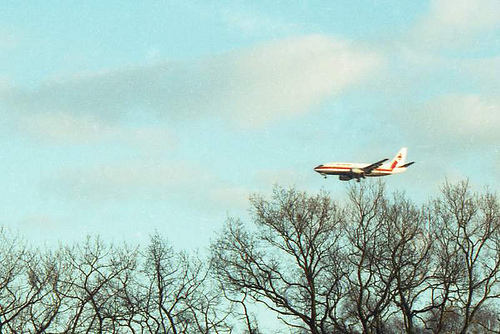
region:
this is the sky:
[19, 22, 53, 45]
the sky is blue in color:
[28, 29, 50, 47]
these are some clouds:
[40, 42, 476, 134]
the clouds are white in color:
[251, 42, 332, 88]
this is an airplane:
[303, 150, 413, 187]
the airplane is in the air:
[313, 147, 413, 177]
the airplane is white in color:
[326, 161, 339, 166]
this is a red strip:
[319, 163, 351, 170]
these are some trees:
[5, 185, 493, 327]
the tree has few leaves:
[268, 202, 323, 229]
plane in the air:
[305, 145, 425, 185]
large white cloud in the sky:
[34, 42, 359, 139]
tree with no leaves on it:
[5, 187, 499, 332]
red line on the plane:
[321, 162, 348, 173]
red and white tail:
[379, 141, 424, 171]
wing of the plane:
[362, 150, 390, 176]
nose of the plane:
[311, 159, 328, 177]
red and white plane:
[282, 135, 435, 195]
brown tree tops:
[2, 185, 497, 329]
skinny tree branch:
[239, 302, 253, 324]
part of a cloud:
[268, 64, 330, 109]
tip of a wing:
[381, 150, 397, 157]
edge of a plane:
[362, 159, 378, 174]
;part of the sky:
[141, 137, 206, 202]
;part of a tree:
[224, 284, 254, 314]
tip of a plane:
[290, 148, 336, 175]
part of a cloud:
[225, 78, 268, 119]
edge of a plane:
[318, 162, 332, 173]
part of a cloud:
[248, 52, 300, 107]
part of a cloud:
[196, 53, 261, 133]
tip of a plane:
[309, 161, 317, 190]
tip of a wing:
[363, 134, 394, 181]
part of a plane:
[329, 160, 347, 177]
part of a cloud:
[239, 90, 294, 158]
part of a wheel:
[319, 168, 330, 183]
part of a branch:
[297, 255, 314, 309]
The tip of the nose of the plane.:
[314, 166, 324, 173]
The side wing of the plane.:
[360, 159, 394, 173]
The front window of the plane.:
[318, 160, 324, 171]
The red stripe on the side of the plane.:
[313, 160, 395, 175]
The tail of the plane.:
[392, 142, 409, 173]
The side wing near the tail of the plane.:
[397, 160, 415, 167]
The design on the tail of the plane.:
[394, 149, 404, 161]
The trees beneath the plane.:
[6, 214, 490, 331]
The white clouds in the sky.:
[12, 30, 474, 209]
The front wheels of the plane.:
[318, 176, 333, 182]